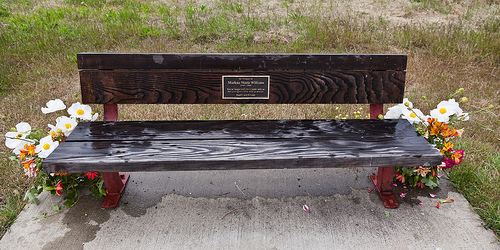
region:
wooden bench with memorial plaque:
[5, 30, 479, 202]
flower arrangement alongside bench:
[379, 83, 497, 205]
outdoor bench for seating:
[33, 50, 455, 210]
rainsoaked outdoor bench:
[6, 33, 497, 222]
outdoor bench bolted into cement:
[24, 44, 475, 248]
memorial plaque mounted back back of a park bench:
[217, 68, 277, 104]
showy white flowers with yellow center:
[2, 100, 87, 153]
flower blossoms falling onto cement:
[395, 164, 466, 214]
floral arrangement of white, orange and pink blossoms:
[2, 98, 105, 208]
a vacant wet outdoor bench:
[10, 16, 493, 237]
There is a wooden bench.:
[50, 46, 441, 211]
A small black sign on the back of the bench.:
[220, 75, 270, 100]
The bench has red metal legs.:
[87, 167, 399, 207]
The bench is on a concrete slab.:
[5, 166, 495, 246]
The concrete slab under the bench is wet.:
[55, 165, 417, 246]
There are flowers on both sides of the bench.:
[10, 95, 465, 205]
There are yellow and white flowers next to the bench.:
[10, 95, 95, 155]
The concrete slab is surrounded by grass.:
[1, 115, 493, 245]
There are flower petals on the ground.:
[410, 190, 455, 212]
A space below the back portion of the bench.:
[80, 100, 400, 116]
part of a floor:
[292, 179, 327, 231]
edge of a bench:
[287, 144, 329, 182]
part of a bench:
[286, 131, 320, 156]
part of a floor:
[304, 200, 334, 231]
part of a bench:
[274, 151, 321, 184]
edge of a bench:
[301, 151, 350, 191]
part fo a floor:
[268, 191, 297, 216]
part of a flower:
[426, 91, 456, 159]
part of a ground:
[439, 96, 492, 161]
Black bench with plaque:
[40, 48, 445, 218]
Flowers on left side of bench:
[1, 95, 103, 213]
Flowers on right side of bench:
[365, 90, 470, 208]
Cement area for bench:
[0, 165, 492, 248]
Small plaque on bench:
[222, 75, 269, 99]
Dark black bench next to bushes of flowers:
[35, 50, 442, 205]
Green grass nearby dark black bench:
[5, 3, 495, 138]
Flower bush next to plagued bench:
[359, 90, 468, 205]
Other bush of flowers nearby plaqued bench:
[0, 93, 110, 223]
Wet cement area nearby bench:
[42, 165, 418, 247]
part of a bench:
[246, 142, 293, 170]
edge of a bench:
[285, 149, 310, 154]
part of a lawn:
[462, 177, 479, 201]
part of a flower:
[439, 108, 442, 115]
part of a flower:
[445, 101, 450, 120]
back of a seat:
[247, 86, 271, 104]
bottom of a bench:
[111, 165, 131, 192]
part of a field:
[325, 24, 348, 49]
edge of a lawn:
[449, 120, 494, 195]